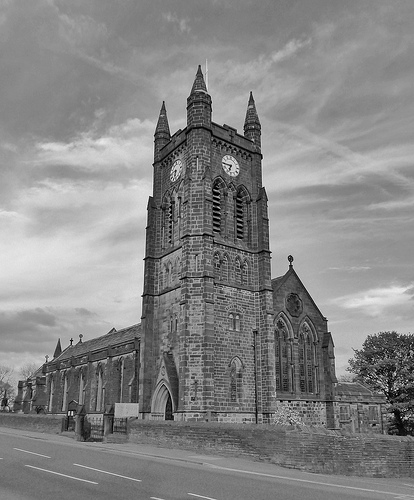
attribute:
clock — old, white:
[219, 152, 241, 179]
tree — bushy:
[345, 331, 413, 435]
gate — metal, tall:
[79, 414, 102, 439]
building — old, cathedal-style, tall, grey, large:
[16, 64, 384, 446]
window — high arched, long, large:
[208, 175, 227, 241]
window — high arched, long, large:
[235, 186, 252, 244]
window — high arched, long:
[160, 190, 176, 248]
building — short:
[272, 251, 327, 427]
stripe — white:
[25, 462, 99, 492]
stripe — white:
[74, 461, 143, 484]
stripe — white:
[12, 445, 54, 461]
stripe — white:
[185, 490, 223, 499]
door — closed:
[160, 393, 176, 419]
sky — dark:
[1, 0, 413, 414]